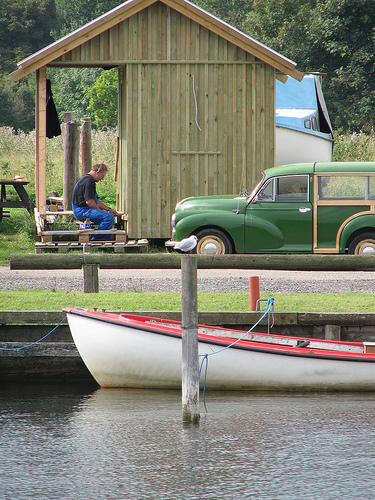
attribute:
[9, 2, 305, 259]
shed — wooden 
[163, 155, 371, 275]
car — brown, green 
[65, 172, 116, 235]
overalls — Blue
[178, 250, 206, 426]
post — wooden 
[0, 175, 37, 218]
picnic table — wooden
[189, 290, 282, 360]
rope — blue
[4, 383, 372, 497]
water — calm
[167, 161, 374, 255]
car — old time, green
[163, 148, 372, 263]
truck — green 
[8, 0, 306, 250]
building — wooden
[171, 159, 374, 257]
vehicle — green 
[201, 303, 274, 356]
tie — Blue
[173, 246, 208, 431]
post — thick, wooden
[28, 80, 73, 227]
post — wooden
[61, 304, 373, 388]
boat — Red , white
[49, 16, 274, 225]
shed — wooden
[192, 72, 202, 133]
cord — white 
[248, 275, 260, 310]
pole — Orange 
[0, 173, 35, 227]
bench — dark, wooden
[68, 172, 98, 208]
shirt — black